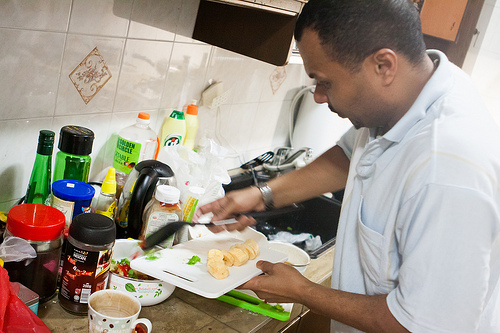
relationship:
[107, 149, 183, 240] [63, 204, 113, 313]
pot on counter coffee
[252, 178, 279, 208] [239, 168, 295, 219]
watch on wrist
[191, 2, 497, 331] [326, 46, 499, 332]
man has shirt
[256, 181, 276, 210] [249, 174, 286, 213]
watch on wrist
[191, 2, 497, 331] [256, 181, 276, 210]
man has watch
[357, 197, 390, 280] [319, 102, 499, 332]
pocket on shirt